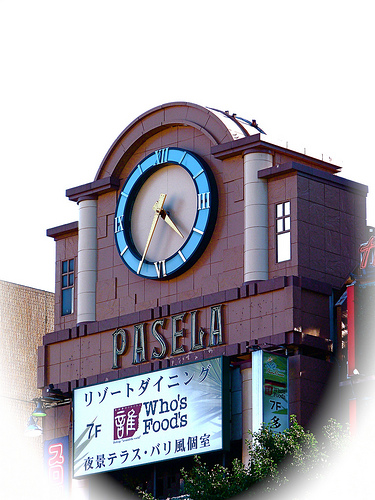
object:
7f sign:
[252, 350, 290, 450]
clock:
[113, 147, 218, 280]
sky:
[0, 0, 375, 293]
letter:
[190, 310, 207, 351]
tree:
[136, 414, 351, 500]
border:
[113, 147, 218, 281]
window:
[275, 202, 292, 264]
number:
[154, 146, 168, 165]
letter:
[151, 318, 168, 359]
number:
[154, 259, 167, 278]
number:
[197, 192, 210, 210]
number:
[114, 215, 124, 234]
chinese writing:
[83, 364, 210, 472]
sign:
[73, 355, 223, 479]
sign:
[103, 268, 291, 481]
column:
[243, 152, 273, 282]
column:
[77, 200, 97, 323]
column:
[241, 368, 252, 476]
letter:
[112, 328, 129, 369]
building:
[36, 100, 368, 499]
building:
[0, 279, 55, 499]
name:
[143, 394, 187, 435]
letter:
[208, 303, 223, 346]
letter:
[170, 312, 188, 356]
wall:
[64, 167, 298, 358]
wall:
[3, 294, 53, 396]